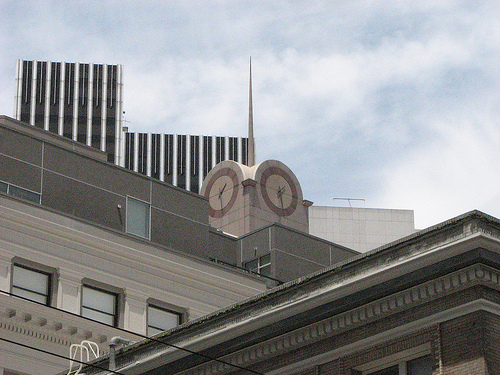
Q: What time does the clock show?
A: 2:30.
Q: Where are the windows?
A: On the side of the building.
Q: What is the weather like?
A: Partly cloudy.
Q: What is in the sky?
A: Clouds.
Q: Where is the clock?
A: On top of the building.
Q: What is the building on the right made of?
A: Brick.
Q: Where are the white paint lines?
A: Near the top of the building.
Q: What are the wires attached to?
A: Side of the building.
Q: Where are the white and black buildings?
A: Behind the others.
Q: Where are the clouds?
A: In the sky.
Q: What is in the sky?
A: Clouds.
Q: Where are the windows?
A: On the buildings.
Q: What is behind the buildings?
A: The sky.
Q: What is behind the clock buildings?
A: Towers.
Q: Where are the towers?
A: Behind the clock building.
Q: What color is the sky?
A: Blue.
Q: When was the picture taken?
A: Daytime.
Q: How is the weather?
A: Cloudy.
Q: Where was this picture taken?
A: City center.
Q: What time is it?
A: 1:30.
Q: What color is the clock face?
A: White.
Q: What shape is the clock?
A: Round.